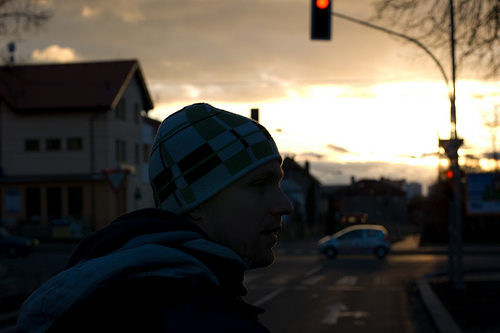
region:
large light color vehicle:
[314, 219, 392, 263]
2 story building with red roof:
[1, 56, 163, 252]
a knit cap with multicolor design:
[138, 100, 283, 213]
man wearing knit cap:
[0, 99, 307, 331]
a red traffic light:
[303, 0, 334, 45]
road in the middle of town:
[229, 231, 499, 332]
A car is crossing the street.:
[311, 222, 393, 264]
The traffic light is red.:
[305, 0, 335, 41]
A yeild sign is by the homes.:
[102, 162, 132, 214]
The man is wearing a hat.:
[128, 102, 298, 325]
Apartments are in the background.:
[3, 41, 148, 242]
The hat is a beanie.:
[138, 100, 283, 216]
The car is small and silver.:
[313, 216, 393, 265]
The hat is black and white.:
[145, 98, 283, 211]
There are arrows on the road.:
[321, 297, 371, 332]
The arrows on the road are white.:
[321, 294, 371, 329]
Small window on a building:
[61, 134, 88, 159]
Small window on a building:
[40, 129, 61, 152]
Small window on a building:
[21, 134, 43, 162]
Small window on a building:
[60, 182, 90, 234]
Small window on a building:
[21, 186, 46, 227]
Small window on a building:
[128, 98, 143, 120]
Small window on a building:
[110, 96, 127, 126]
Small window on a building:
[132, 139, 143, 171]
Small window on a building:
[111, 137, 136, 171]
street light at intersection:
[306, 0, 338, 45]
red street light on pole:
[446, 166, 461, 201]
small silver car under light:
[317, 220, 393, 261]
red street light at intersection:
[307, 2, 334, 42]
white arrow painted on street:
[318, 298, 371, 327]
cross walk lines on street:
[331, 270, 361, 292]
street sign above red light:
[439, 138, 466, 180]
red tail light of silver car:
[383, 233, 393, 244]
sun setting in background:
[475, 153, 498, 174]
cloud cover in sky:
[2, 1, 497, 176]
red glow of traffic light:
[311, 0, 331, 38]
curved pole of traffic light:
[310, 1, 455, 137]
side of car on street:
[317, 223, 389, 260]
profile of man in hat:
[20, 102, 292, 332]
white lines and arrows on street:
[252, 268, 370, 323]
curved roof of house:
[2, 59, 150, 231]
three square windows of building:
[26, 135, 83, 152]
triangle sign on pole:
[104, 167, 131, 217]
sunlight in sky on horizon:
[157, 80, 499, 165]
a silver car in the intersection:
[318, 225, 391, 262]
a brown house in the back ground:
[0, 54, 152, 248]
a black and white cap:
[142, 100, 287, 210]